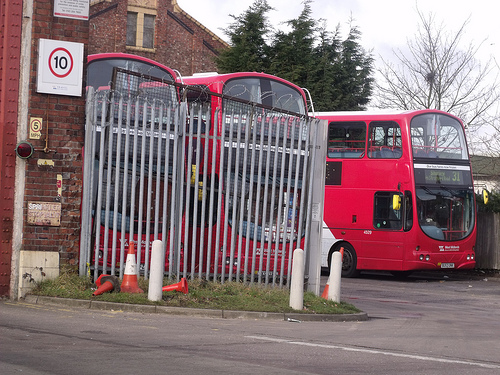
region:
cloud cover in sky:
[185, 1, 497, 154]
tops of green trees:
[219, 3, 373, 112]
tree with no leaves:
[379, 3, 496, 150]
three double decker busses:
[89, 53, 478, 274]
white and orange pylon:
[120, 240, 140, 292]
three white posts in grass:
[147, 238, 343, 308]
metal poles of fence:
[83, 89, 323, 280]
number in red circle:
[49, 45, 74, 77]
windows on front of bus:
[406, 114, 473, 269]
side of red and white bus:
[319, 115, 419, 272]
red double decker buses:
[119, 53, 438, 291]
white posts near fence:
[126, 219, 346, 296]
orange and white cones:
[126, 247, 150, 294]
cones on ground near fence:
[87, 272, 249, 296]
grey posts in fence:
[96, 104, 318, 294]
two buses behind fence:
[111, 41, 322, 301]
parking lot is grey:
[373, 297, 454, 367]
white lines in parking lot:
[249, 294, 434, 371]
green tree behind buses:
[249, 29, 394, 127]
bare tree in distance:
[380, 9, 477, 141]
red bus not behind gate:
[304, 73, 471, 296]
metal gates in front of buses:
[72, 113, 329, 287]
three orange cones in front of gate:
[69, 248, 209, 325]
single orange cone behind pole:
[324, 229, 346, 331]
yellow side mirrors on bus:
[385, 175, 497, 225]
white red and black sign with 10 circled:
[27, 28, 89, 106]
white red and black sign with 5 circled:
[23, 110, 55, 150]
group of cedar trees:
[224, 1, 371, 118]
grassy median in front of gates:
[5, 273, 350, 312]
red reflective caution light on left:
[22, 136, 37, 165]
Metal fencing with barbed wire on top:
[83, 63, 324, 290]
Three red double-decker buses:
[85, 52, 475, 279]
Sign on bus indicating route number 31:
[420, 165, 460, 180]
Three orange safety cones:
[90, 240, 186, 300]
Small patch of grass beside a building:
[30, 270, 360, 315]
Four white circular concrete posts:
[147, 237, 343, 307]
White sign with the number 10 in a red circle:
[33, 36, 83, 96]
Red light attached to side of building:
[15, 140, 32, 158]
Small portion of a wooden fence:
[475, 206, 497, 271]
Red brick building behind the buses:
[90, 1, 234, 75]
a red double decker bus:
[309, 108, 477, 280]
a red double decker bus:
[101, 73, 316, 285]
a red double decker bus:
[85, 53, 189, 273]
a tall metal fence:
[87, 68, 325, 298]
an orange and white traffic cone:
[119, 240, 141, 291]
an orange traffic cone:
[90, 274, 119, 297]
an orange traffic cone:
[162, 277, 190, 294]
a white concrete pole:
[289, 248, 304, 310]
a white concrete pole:
[329, 250, 342, 303]